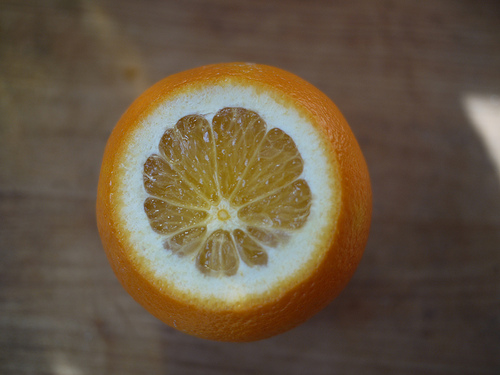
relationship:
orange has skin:
[72, 54, 388, 362] [181, 89, 245, 105]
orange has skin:
[72, 54, 388, 362] [226, 62, 294, 89]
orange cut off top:
[72, 54, 388, 362] [101, 63, 365, 313]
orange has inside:
[72, 54, 388, 362] [133, 95, 320, 248]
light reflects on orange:
[182, 131, 248, 185] [72, 54, 388, 362]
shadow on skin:
[283, 255, 364, 342] [226, 62, 294, 89]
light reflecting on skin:
[182, 131, 248, 185] [226, 62, 294, 89]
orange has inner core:
[72, 54, 388, 362] [203, 186, 241, 237]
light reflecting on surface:
[182, 131, 248, 185] [149, 116, 284, 244]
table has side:
[345, 42, 446, 148] [462, 87, 498, 131]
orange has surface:
[72, 54, 388, 362] [149, 116, 284, 244]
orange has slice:
[72, 54, 388, 362] [238, 184, 320, 231]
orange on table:
[72, 54, 388, 362] [345, 42, 446, 148]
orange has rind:
[72, 54, 388, 362] [284, 232, 337, 281]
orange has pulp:
[72, 54, 388, 362] [248, 154, 286, 192]